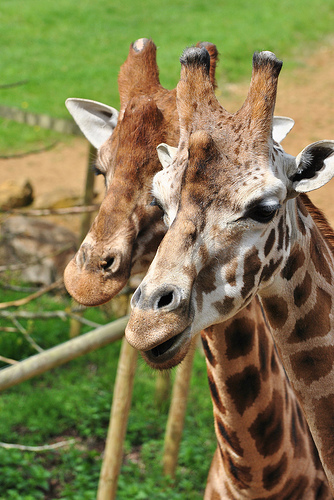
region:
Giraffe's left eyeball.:
[236, 179, 285, 231]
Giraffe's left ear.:
[295, 141, 332, 192]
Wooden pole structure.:
[0, 327, 137, 487]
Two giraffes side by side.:
[56, 45, 333, 496]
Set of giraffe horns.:
[181, 47, 281, 132]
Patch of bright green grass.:
[5, 33, 94, 97]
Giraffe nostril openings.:
[74, 245, 122, 273]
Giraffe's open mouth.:
[122, 324, 194, 372]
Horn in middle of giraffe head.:
[184, 129, 225, 183]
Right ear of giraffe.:
[64, 94, 115, 147]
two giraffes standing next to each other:
[27, 35, 331, 498]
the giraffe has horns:
[159, 45, 277, 145]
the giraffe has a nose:
[126, 279, 184, 314]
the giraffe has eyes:
[145, 175, 286, 238]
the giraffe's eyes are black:
[146, 174, 290, 230]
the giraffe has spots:
[208, 202, 332, 371]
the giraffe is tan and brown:
[149, 195, 333, 433]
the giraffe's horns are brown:
[173, 45, 280, 148]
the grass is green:
[1, 2, 328, 143]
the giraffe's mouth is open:
[110, 324, 194, 364]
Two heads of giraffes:
[60, 44, 333, 373]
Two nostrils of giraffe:
[129, 280, 192, 310]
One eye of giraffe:
[247, 193, 280, 223]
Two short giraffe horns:
[183, 46, 283, 135]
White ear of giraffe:
[65, 93, 124, 149]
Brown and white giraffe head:
[147, 111, 318, 331]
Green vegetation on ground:
[2, 378, 95, 494]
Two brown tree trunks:
[96, 344, 193, 498]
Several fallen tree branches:
[0, 265, 85, 345]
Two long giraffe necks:
[208, 322, 332, 486]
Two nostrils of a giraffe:
[129, 277, 193, 313]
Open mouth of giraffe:
[123, 318, 191, 373]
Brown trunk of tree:
[99, 344, 128, 497]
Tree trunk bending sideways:
[1, 293, 132, 393]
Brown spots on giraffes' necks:
[205, 287, 332, 497]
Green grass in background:
[4, 1, 323, 114]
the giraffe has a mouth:
[120, 327, 189, 365]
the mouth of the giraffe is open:
[115, 328, 198, 360]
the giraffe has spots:
[225, 359, 293, 454]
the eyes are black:
[149, 179, 290, 233]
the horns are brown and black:
[161, 46, 282, 137]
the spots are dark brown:
[219, 362, 288, 424]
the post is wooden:
[92, 338, 129, 487]